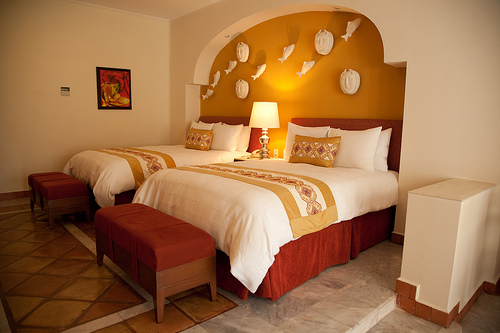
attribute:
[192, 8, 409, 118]
decoration — ocean-themed, white, yellow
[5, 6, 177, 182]
wall — white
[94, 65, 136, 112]
painting — black-framed, artwork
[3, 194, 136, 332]
tiles — brown, diamond pattern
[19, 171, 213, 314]
ottoman — wooden, red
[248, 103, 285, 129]
shade — white, beige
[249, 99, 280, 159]
lamp — metal, on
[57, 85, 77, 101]
thermostat — digital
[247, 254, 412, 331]
tiles — marble, white, grey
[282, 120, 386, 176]
pillow — red, ochre, white, orange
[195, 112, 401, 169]
headboard — red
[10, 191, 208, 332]
floor tile — orange, brown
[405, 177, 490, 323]
pillar — empty, white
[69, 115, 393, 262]
bed — matching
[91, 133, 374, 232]
bedspread — white, gold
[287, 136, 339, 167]
pillow — decorative, gold, small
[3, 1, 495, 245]
walls — white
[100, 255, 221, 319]
stool — brown, wooden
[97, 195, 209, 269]
cloth — brown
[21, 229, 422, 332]
floor — tile, marble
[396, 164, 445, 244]
wall — small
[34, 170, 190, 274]
cushion — orange